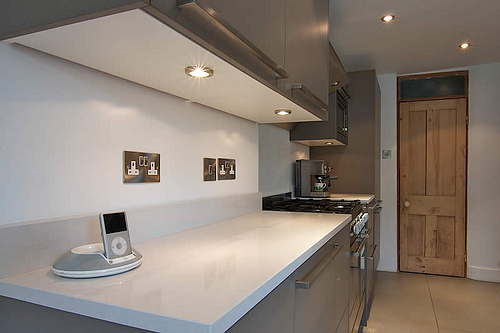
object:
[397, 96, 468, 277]
door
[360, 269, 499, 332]
floor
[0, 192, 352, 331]
counter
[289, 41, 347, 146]
cabinet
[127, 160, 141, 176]
plug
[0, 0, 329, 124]
cabinet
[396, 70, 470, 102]
window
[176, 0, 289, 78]
handles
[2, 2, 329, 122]
cabinets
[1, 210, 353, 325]
countertop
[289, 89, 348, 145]
microwave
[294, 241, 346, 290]
handle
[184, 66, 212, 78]
light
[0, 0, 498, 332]
kitchen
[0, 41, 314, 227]
wall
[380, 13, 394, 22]
light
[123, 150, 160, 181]
picture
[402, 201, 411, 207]
knob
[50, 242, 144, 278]
charging station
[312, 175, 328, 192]
pot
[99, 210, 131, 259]
ipod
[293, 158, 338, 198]
coffee maker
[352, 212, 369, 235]
control dials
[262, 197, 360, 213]
kitchen stove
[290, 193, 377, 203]
counter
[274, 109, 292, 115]
light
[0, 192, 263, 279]
backsplash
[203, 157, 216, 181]
picture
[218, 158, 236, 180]
picture